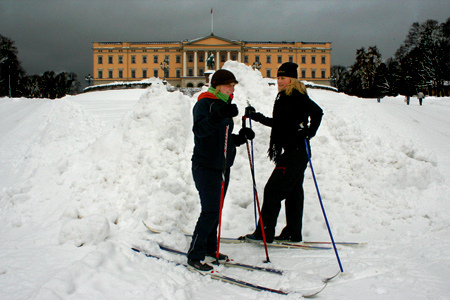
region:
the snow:
[34, 140, 130, 264]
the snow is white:
[36, 126, 104, 201]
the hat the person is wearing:
[215, 69, 234, 84]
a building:
[95, 46, 176, 73]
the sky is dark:
[30, 5, 109, 40]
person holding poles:
[217, 128, 227, 255]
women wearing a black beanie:
[272, 57, 299, 74]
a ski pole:
[314, 195, 337, 231]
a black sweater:
[273, 92, 305, 161]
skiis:
[223, 252, 281, 275]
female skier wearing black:
[183, 65, 254, 277]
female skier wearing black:
[248, 60, 323, 245]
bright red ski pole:
[212, 112, 228, 269]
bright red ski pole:
[233, 108, 269, 261]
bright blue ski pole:
[294, 116, 344, 271]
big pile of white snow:
[0, 56, 449, 297]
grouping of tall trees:
[331, 14, 449, 108]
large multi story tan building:
[85, 33, 342, 97]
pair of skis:
[123, 236, 344, 299]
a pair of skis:
[178, 218, 360, 259]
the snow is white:
[351, 137, 419, 232]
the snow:
[82, 167, 134, 239]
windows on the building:
[92, 52, 135, 65]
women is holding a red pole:
[210, 184, 229, 264]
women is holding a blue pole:
[302, 138, 325, 183]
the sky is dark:
[27, 11, 78, 48]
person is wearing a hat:
[214, 69, 233, 79]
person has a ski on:
[214, 268, 246, 287]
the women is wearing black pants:
[272, 161, 304, 203]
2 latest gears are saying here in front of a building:
[6, 6, 446, 298]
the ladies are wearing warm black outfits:
[177, 57, 348, 289]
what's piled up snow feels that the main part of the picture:
[8, 2, 449, 291]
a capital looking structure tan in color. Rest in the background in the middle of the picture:
[62, 2, 384, 299]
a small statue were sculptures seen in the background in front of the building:
[202, 52, 222, 71]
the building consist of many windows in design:
[69, 19, 378, 298]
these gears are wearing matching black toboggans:
[125, 60, 353, 295]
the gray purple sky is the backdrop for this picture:
[0, 19, 445, 59]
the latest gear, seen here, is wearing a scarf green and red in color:
[161, 54, 254, 286]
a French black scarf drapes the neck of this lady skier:
[240, 43, 327, 262]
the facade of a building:
[89, 37, 333, 84]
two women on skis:
[132, 58, 369, 297]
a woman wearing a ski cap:
[274, 56, 304, 95]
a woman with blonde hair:
[268, 57, 311, 100]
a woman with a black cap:
[204, 67, 242, 109]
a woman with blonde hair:
[202, 65, 242, 106]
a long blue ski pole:
[301, 137, 380, 277]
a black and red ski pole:
[212, 121, 226, 268]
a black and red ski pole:
[242, 117, 272, 261]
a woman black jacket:
[246, 53, 321, 152]